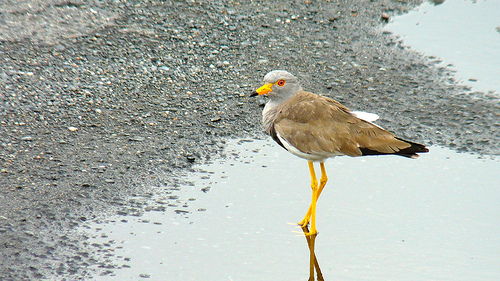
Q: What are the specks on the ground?
A: Stones and shells.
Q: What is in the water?
A: A small bird.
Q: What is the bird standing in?
A: A puddle.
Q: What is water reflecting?
A: The bird's legs.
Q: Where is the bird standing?
A: In a puddle.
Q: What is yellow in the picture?
A: Bird legs and beak.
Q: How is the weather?
A: Wet.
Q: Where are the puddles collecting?
A: Concrete.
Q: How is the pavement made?
A: Of concrete.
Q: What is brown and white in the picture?
A: A bird.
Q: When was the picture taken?
A: Afternoon.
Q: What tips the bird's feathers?
A: Black.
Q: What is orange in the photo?
A: The bird's eye.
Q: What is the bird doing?
A: Wading.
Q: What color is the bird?
A: Gray, brown, and yellow.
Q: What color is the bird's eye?
A: Orange and black.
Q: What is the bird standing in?
A: Water.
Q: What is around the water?
A: Gravel.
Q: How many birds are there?
A: One.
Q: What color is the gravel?
A: Gray.